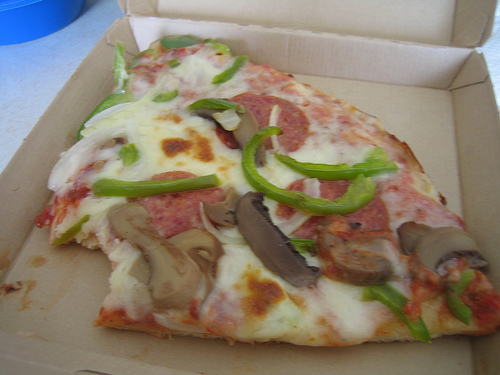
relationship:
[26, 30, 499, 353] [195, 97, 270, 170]
pizza has mushroom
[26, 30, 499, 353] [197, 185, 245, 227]
pizza has mushroom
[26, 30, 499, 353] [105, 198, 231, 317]
pizza has mushroom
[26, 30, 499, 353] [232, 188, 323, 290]
pizza has mushroom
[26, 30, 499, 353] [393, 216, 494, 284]
pizza has mushroom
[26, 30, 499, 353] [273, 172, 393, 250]
pizza with pepperoni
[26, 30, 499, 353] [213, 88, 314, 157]
pizza with pepperoni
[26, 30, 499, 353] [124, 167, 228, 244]
pizza with pepperoni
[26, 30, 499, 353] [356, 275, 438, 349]
pizza has peppers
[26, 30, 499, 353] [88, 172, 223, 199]
pizza has peppers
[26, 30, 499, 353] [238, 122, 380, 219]
pizza has peppers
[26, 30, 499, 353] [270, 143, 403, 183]
pizza has peppers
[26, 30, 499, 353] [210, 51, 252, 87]
pizza has peppers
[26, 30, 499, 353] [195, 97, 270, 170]
pizza with mushroom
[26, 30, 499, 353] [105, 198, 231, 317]
pizza with mushroom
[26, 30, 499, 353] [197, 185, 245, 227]
pizza with mushroom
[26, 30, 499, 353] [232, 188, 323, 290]
pizza with mushroom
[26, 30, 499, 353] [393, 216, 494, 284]
pizza with mushroom